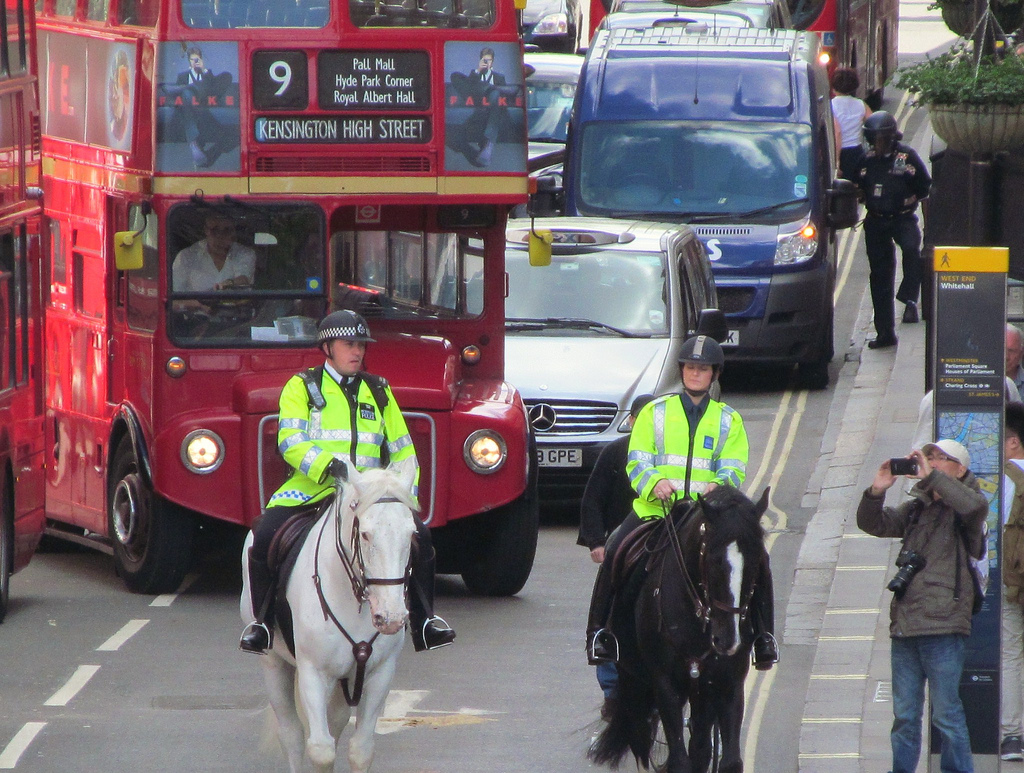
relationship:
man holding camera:
[846, 439, 1003, 771] [882, 455, 925, 476]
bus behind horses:
[17, 2, 536, 595] [207, 465, 774, 764]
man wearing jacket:
[223, 299, 464, 658] [269, 364, 432, 513]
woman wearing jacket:
[573, 332, 815, 684] [612, 379, 764, 512]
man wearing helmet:
[238, 310, 457, 654] [299, 294, 375, 343]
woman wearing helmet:
[586, 334, 780, 671] [662, 328, 729, 374]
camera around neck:
[882, 553, 927, 593] [921, 477, 956, 504]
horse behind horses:
[239, 455, 453, 773] [207, 465, 774, 764]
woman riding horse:
[586, 334, 780, 671] [580, 484, 821, 754]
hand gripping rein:
[320, 460, 346, 484] [310, 498, 386, 704]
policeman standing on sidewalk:
[838, 103, 946, 351] [844, 327, 914, 745]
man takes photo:
[855, 439, 987, 773] [0, 8, 1015, 771]